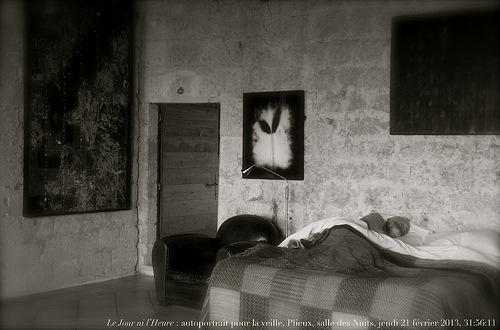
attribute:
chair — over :
[153, 214, 283, 306]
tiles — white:
[51, 290, 148, 324]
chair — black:
[149, 215, 275, 309]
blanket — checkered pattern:
[200, 224, 498, 328]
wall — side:
[109, 37, 186, 267]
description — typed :
[106, 315, 499, 329]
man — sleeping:
[295, 193, 428, 270]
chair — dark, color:
[150, 212, 288, 315]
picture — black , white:
[207, 69, 331, 187]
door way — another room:
[142, 95, 224, 279]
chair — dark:
[151, 204, 298, 318]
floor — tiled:
[17, 270, 145, 328]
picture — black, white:
[235, 85, 311, 184]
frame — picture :
[234, 80, 312, 191]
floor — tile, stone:
[47, 290, 155, 316]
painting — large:
[25, 6, 132, 210]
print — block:
[262, 270, 322, 313]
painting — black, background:
[244, 94, 304, 177]